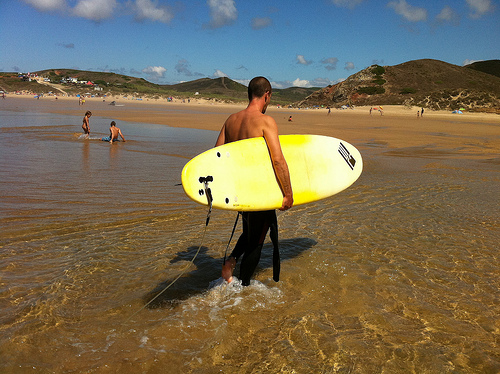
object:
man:
[214, 76, 294, 285]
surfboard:
[179, 133, 365, 213]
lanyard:
[125, 176, 218, 335]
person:
[94, 121, 130, 145]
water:
[0, 99, 499, 373]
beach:
[0, 90, 500, 161]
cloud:
[129, 0, 176, 27]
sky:
[0, 0, 499, 91]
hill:
[307, 57, 499, 104]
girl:
[82, 110, 92, 135]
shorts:
[100, 134, 115, 144]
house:
[84, 76, 94, 87]